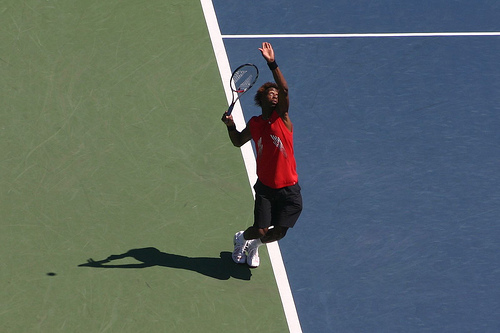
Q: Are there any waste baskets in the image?
A: No, there are no waste baskets.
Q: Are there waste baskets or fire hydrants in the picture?
A: No, there are no waste baskets or fire hydrants.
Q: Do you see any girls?
A: No, there are no girls.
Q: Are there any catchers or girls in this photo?
A: No, there are no girls or catchers.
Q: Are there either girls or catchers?
A: No, there are no girls or catchers.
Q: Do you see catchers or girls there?
A: No, there are no girls or catchers.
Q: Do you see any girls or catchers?
A: No, there are no girls or catchers.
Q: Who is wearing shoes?
A: The man is wearing shoes.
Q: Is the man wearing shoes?
A: Yes, the man is wearing shoes.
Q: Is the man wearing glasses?
A: No, the man is wearing shoes.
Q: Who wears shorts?
A: The man wears shorts.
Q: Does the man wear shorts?
A: Yes, the man wears shorts.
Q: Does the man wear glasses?
A: No, the man wears shorts.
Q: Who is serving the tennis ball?
A: The man is serving the tennis ball.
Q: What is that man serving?
A: The man is serving a tennis ball.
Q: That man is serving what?
A: The man is serving a tennis ball.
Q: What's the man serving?
A: The man is serving a tennis ball.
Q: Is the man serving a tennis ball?
A: Yes, the man is serving a tennis ball.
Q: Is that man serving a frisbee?
A: No, the man is serving a tennis ball.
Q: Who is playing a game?
A: The man is playing a game.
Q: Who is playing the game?
A: The man is playing a game.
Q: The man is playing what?
A: The man is playing a game.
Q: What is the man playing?
A: The man is playing a game.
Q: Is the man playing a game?
A: Yes, the man is playing a game.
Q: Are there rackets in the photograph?
A: Yes, there is a racket.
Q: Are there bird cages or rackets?
A: Yes, there is a racket.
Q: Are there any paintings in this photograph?
A: No, there are no paintings.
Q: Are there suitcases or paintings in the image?
A: No, there are no paintings or suitcases.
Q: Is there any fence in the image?
A: No, there are no fences.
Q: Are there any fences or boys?
A: No, there are no fences or boys.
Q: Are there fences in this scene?
A: No, there are no fences.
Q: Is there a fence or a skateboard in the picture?
A: No, there are no fences or skateboards.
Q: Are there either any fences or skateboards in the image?
A: No, there are no fences or skateboards.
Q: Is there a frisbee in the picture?
A: No, there are no frisbees.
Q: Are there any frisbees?
A: No, there are no frisbees.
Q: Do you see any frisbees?
A: No, there are no frisbees.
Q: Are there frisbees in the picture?
A: No, there are no frisbees.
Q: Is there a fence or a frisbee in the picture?
A: No, there are no frisbees or fences.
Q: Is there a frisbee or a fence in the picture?
A: No, there are no frisbees or fences.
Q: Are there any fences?
A: No, there are no fences.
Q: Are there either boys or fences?
A: No, there are no fences or boys.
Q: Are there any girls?
A: No, there are no girls.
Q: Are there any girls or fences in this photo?
A: No, there are no girls or fences.